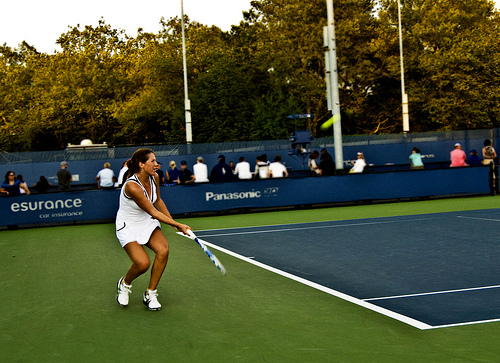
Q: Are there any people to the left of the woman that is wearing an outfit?
A: Yes, there is a person to the left of the woman.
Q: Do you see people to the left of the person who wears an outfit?
A: Yes, there is a person to the left of the woman.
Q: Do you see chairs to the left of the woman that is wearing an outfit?
A: No, there is a person to the left of the woman.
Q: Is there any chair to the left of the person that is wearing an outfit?
A: No, there is a person to the left of the woman.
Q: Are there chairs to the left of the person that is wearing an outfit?
A: No, there is a person to the left of the woman.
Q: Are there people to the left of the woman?
A: Yes, there is a person to the left of the woman.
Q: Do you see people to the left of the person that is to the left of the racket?
A: Yes, there is a person to the left of the woman.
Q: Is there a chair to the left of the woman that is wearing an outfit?
A: No, there is a person to the left of the woman.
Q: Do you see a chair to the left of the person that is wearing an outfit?
A: No, there is a person to the left of the woman.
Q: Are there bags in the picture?
A: No, there are no bags.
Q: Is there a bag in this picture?
A: No, there are no bags.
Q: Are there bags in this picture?
A: No, there are no bags.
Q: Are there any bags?
A: No, there are no bags.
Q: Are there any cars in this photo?
A: No, there are no cars.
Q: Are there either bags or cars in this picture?
A: No, there are no cars or bags.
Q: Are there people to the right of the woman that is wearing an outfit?
A: Yes, there is a person to the right of the woman.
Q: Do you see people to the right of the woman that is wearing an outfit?
A: Yes, there is a person to the right of the woman.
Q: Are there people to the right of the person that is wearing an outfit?
A: Yes, there is a person to the right of the woman.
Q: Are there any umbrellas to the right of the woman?
A: No, there is a person to the right of the woman.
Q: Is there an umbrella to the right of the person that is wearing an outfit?
A: No, there is a person to the right of the woman.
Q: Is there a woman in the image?
A: Yes, there is a woman.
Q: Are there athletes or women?
A: Yes, there is a woman.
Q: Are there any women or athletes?
A: Yes, there is a woman.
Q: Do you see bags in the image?
A: No, there are no bags.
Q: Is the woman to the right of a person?
A: No, the woman is to the left of a person.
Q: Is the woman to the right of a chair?
A: No, the woman is to the right of a person.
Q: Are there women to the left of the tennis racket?
A: Yes, there is a woman to the left of the tennis racket.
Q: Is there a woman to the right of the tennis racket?
A: No, the woman is to the left of the tennis racket.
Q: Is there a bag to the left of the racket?
A: No, there is a woman to the left of the racket.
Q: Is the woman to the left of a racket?
A: Yes, the woman is to the left of a racket.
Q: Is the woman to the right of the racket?
A: No, the woman is to the left of the racket.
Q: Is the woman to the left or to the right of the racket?
A: The woman is to the left of the racket.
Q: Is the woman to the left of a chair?
A: No, the woman is to the left of a person.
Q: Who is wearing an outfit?
A: The woman is wearing an outfit.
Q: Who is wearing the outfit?
A: The woman is wearing an outfit.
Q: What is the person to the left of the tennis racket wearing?
A: The woman is wearing an outfit.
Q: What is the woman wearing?
A: The woman is wearing an outfit.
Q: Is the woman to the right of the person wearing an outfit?
A: Yes, the woman is wearing an outfit.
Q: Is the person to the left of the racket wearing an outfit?
A: Yes, the woman is wearing an outfit.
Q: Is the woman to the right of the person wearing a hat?
A: No, the woman is wearing an outfit.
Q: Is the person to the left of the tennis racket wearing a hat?
A: No, the woman is wearing an outfit.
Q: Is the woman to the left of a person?
A: No, the woman is to the right of a person.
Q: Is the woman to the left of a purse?
A: No, the woman is to the left of a person.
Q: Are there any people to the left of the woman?
A: Yes, there is a person to the left of the woman.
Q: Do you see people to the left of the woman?
A: Yes, there is a person to the left of the woman.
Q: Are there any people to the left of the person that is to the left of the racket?
A: Yes, there is a person to the left of the woman.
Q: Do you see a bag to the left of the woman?
A: No, there is a person to the left of the woman.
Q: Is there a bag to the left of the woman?
A: No, there is a person to the left of the woman.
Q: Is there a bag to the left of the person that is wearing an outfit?
A: No, there is a person to the left of the woman.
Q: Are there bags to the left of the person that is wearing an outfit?
A: No, there is a person to the left of the woman.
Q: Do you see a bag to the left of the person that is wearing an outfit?
A: No, there is a person to the left of the woman.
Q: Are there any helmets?
A: No, there are no helmets.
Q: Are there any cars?
A: No, there are no cars.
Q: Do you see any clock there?
A: No, there are no clocks.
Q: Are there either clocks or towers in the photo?
A: No, there are no clocks or towers.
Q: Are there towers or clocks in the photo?
A: No, there are no clocks or towers.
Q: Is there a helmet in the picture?
A: No, there are no helmets.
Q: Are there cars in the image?
A: No, there are no cars.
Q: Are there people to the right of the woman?
A: Yes, there is a person to the right of the woman.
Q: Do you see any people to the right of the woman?
A: Yes, there is a person to the right of the woman.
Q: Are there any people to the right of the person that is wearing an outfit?
A: Yes, there is a person to the right of the woman.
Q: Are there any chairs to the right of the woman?
A: No, there is a person to the right of the woman.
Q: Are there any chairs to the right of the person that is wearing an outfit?
A: No, there is a person to the right of the woman.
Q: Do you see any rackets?
A: Yes, there is a racket.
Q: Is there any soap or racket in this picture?
A: Yes, there is a racket.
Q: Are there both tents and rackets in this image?
A: No, there is a racket but no tents.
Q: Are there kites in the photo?
A: No, there are no kites.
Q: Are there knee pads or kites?
A: No, there are no kites or knee pads.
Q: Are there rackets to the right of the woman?
A: Yes, there is a racket to the right of the woman.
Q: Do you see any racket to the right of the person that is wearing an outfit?
A: Yes, there is a racket to the right of the woman.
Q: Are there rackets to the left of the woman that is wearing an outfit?
A: No, the racket is to the right of the woman.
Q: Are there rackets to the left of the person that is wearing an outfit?
A: No, the racket is to the right of the woman.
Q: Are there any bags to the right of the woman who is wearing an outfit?
A: No, there is a racket to the right of the woman.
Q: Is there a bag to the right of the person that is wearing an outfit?
A: No, there is a racket to the right of the woman.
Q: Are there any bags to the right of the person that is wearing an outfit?
A: No, there is a racket to the right of the woman.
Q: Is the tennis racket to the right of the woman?
A: Yes, the tennis racket is to the right of the woman.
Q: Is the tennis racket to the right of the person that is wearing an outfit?
A: Yes, the tennis racket is to the right of the woman.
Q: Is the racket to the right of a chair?
A: No, the racket is to the right of the woman.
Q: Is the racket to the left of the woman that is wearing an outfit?
A: No, the racket is to the right of the woman.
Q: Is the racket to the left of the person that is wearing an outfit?
A: No, the racket is to the right of the woman.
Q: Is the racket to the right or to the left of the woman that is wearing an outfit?
A: The racket is to the right of the woman.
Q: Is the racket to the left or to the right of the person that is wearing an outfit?
A: The racket is to the right of the woman.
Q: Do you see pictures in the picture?
A: No, there are no pictures.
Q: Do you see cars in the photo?
A: No, there are no cars.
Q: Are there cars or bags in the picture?
A: No, there are no cars or bags.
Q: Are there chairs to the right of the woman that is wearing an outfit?
A: No, there is a person to the right of the woman.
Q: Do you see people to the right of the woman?
A: Yes, there is a person to the right of the woman.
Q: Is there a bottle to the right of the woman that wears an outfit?
A: No, there is a person to the right of the woman.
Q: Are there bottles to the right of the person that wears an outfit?
A: No, there is a person to the right of the woman.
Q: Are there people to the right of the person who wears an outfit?
A: Yes, there is a person to the right of the woman.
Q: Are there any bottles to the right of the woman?
A: No, there is a person to the right of the woman.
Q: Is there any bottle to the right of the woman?
A: No, there is a person to the right of the woman.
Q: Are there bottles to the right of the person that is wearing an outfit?
A: No, there is a person to the right of the woman.